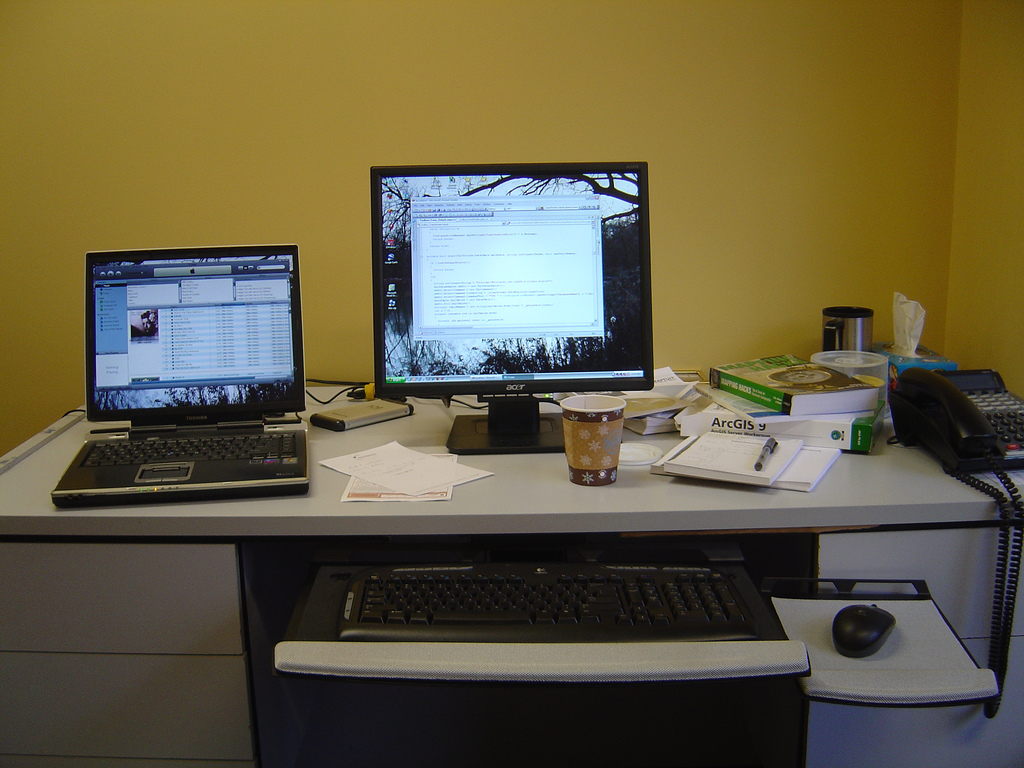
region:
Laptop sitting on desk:
[1, 112, 362, 536]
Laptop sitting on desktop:
[23, 183, 328, 551]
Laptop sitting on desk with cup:
[45, 203, 674, 529]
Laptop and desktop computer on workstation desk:
[23, 69, 707, 541]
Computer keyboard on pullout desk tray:
[234, 518, 873, 738]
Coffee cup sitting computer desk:
[535, 383, 666, 511]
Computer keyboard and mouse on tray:
[267, 533, 1020, 724]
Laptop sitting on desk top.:
[75, 246, 335, 516]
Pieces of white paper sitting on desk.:
[334, 440, 468, 504]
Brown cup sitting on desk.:
[562, 397, 633, 509]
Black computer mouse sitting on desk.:
[821, 597, 913, 656]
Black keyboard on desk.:
[354, 575, 740, 633]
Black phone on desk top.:
[906, 376, 1021, 491]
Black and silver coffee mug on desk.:
[809, 301, 880, 352]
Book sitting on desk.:
[710, 356, 870, 420]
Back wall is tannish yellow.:
[31, 151, 1022, 364]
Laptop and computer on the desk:
[0, 157, 1009, 767]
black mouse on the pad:
[826, 599, 899, 664]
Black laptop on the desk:
[43, 238, 313, 515]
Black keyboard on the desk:
[326, 554, 770, 647]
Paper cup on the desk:
[554, 393, 630, 491]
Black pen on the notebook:
[661, 428, 813, 496]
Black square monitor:
[364, 157, 658, 402]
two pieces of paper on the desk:
[311, 437, 498, 507]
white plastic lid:
[611, 435, 668, 473]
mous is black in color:
[827, 585, 917, 677]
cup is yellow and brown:
[558, 387, 615, 476]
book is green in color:
[710, 348, 856, 438]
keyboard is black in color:
[339, 554, 777, 662]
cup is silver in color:
[818, 295, 869, 354]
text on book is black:
[700, 409, 793, 438]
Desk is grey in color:
[58, 384, 1017, 550]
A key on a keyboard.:
[397, 585, 417, 601]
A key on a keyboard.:
[508, 596, 525, 607]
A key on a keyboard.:
[527, 583, 540, 593]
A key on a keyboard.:
[558, 589, 574, 616]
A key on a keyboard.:
[439, 599, 449, 604]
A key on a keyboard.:
[474, 588, 487, 605]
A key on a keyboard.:
[691, 579, 705, 593]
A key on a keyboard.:
[647, 586, 658, 599]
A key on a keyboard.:
[565, 592, 597, 618]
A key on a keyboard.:
[540, 602, 567, 621]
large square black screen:
[366, 153, 660, 401]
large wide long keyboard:
[336, 562, 793, 654]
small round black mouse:
[827, 603, 894, 660]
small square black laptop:
[53, 240, 313, 513]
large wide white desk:
[4, 394, 1023, 765]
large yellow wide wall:
[4, 0, 1023, 502]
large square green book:
[710, 349, 898, 419]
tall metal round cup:
[823, 305, 880, 363]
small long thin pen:
[748, 432, 788, 478]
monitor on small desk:
[358, 125, 654, 407]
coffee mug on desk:
[550, 384, 636, 490]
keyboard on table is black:
[324, 556, 774, 674]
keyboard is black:
[312, 549, 793, 686]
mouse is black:
[822, 598, 903, 663]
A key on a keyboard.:
[455, 590, 471, 606]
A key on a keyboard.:
[483, 589, 502, 608]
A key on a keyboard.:
[528, 583, 554, 603]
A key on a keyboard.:
[537, 601, 564, 627]